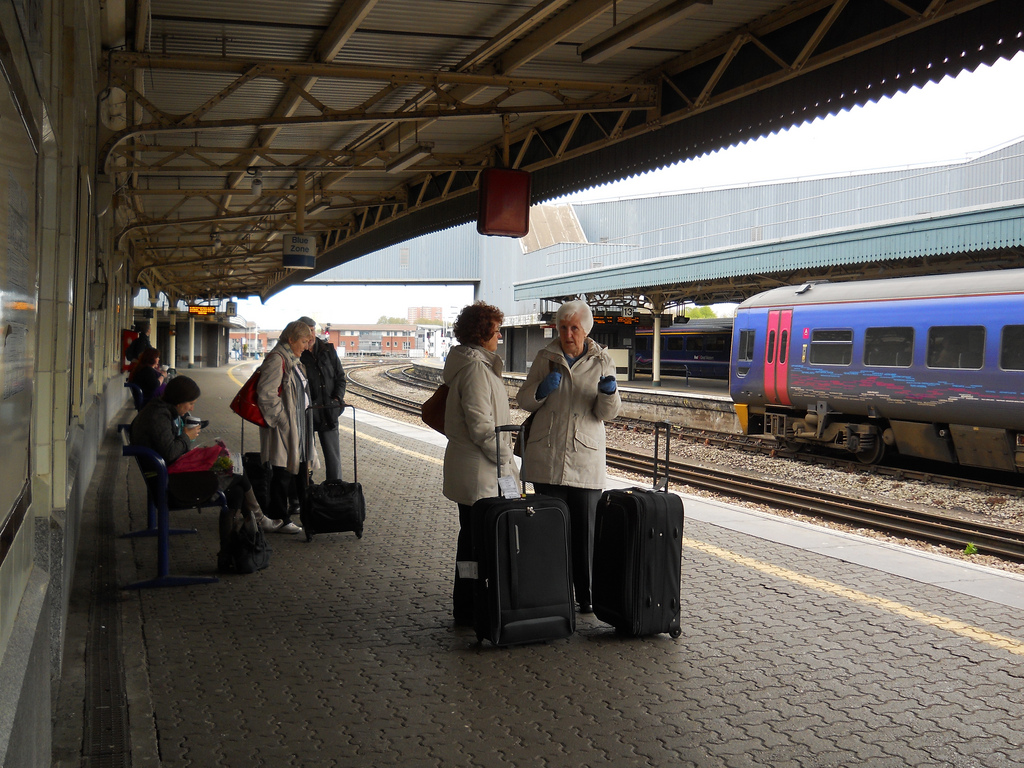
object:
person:
[517, 300, 624, 613]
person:
[287, 315, 348, 485]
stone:
[654, 711, 711, 738]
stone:
[614, 704, 666, 730]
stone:
[586, 733, 640, 763]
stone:
[501, 690, 545, 715]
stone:
[540, 696, 586, 720]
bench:
[113, 423, 230, 591]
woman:
[128, 375, 284, 536]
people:
[255, 321, 323, 535]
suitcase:
[591, 422, 684, 639]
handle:
[495, 424, 527, 498]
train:
[725, 268, 1024, 484]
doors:
[764, 310, 781, 407]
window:
[807, 327, 856, 367]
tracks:
[337, 360, 1024, 575]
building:
[318, 323, 416, 358]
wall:
[0, 0, 132, 768]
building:
[132, 288, 230, 370]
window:
[862, 326, 915, 369]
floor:
[102, 357, 1024, 767]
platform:
[50, 360, 1024, 768]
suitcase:
[455, 425, 576, 646]